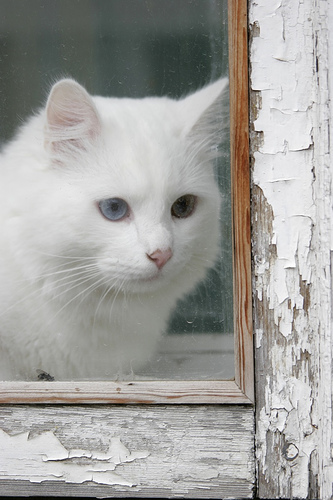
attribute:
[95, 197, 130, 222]
eye — blue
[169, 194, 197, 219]
eye — blue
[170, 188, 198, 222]
eye — light blue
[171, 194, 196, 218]
eye — green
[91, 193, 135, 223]
eye — blue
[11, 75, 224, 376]
cat — white, fluffy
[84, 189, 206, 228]
eyes — Heterochromia iridium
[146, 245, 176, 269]
cat's nose — light, pink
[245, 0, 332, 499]
frame — chipping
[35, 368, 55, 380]
fly — small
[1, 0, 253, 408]
frame — painted, chipped, white, wood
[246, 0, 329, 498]
paint — chipping 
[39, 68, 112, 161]
ear — light pink, white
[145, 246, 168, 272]
nose — pink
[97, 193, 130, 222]
eye — blue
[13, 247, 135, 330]
whiskers — white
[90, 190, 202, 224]
eyes — blue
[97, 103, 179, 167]
fur — white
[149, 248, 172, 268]
nose — pink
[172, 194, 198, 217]
eye — light green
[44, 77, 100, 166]
cat's ear — white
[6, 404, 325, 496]
paint — chipping 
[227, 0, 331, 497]
paint — chipping 